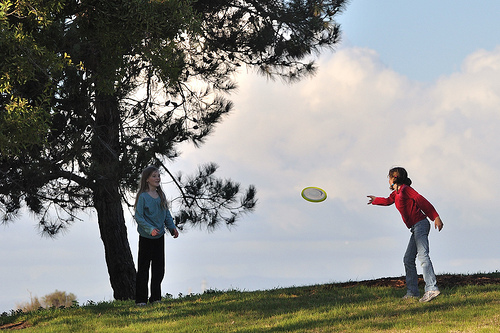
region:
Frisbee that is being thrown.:
[285, 172, 333, 213]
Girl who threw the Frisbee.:
[356, 160, 456, 314]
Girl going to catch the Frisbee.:
[124, 167, 198, 296]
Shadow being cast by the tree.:
[254, 285, 319, 308]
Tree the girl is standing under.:
[42, 119, 133, 294]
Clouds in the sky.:
[369, 127, 482, 157]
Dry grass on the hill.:
[15, 295, 85, 307]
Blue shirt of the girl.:
[138, 203, 168, 228]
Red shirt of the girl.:
[395, 195, 445, 215]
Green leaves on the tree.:
[15, 119, 62, 157]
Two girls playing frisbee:
[127, 157, 450, 309]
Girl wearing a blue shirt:
[132, 156, 184, 314]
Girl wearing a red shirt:
[361, 156, 456, 308]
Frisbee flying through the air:
[289, 177, 339, 210]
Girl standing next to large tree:
[2, 85, 227, 304]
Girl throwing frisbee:
[294, 148, 464, 314]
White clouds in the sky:
[255, 92, 484, 161]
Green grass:
[172, 300, 460, 332]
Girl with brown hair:
[365, 162, 451, 304]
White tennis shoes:
[400, 290, 460, 308]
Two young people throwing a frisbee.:
[41, 73, 462, 321]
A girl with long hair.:
[124, 155, 179, 295]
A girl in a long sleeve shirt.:
[128, 166, 188, 249]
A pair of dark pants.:
[128, 227, 183, 303]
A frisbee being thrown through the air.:
[291, 173, 355, 208]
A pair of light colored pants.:
[386, 217, 451, 290]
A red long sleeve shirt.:
[359, 159, 451, 227]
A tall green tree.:
[17, 32, 145, 304]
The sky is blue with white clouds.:
[351, 19, 476, 146]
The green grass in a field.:
[206, 283, 383, 326]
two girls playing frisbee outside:
[132, 162, 444, 311]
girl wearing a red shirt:
[365, 165, 444, 303]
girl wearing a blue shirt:
[130, 165, 180, 303]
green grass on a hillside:
[0, 265, 495, 330]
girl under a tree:
[0, 2, 349, 308]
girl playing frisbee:
[302, 165, 445, 304]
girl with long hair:
[132, 163, 179, 303]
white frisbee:
[297, 185, 327, 203]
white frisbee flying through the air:
[299, 184, 327, 201]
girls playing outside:
[135, 160, 444, 305]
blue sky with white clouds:
[6, 4, 494, 271]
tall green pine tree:
[0, 3, 339, 286]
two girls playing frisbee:
[119, 150, 456, 307]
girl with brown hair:
[366, 162, 448, 304]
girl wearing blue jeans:
[362, 166, 449, 311]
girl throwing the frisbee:
[299, 158, 454, 306]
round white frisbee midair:
[292, 181, 326, 205]